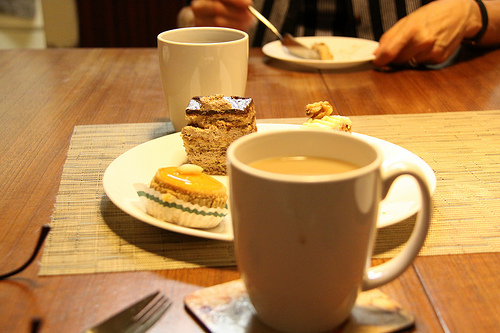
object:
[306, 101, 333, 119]
nut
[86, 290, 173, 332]
fork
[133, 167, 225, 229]
brown dessert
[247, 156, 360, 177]
coffee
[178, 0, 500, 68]
person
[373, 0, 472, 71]
hand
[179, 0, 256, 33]
hand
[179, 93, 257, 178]
cake